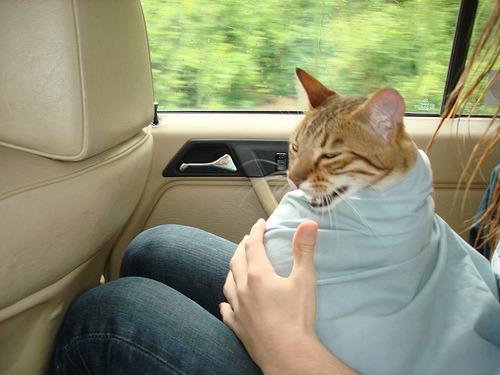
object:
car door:
[135, 2, 482, 212]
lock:
[150, 104, 162, 133]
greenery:
[139, 2, 499, 128]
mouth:
[295, 183, 349, 210]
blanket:
[245, 146, 498, 370]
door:
[104, 1, 498, 302]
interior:
[4, 1, 497, 373]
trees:
[143, 3, 497, 122]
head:
[279, 60, 427, 224]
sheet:
[238, 146, 498, 373]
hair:
[410, 4, 498, 262]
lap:
[60, 268, 238, 374]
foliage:
[142, 4, 498, 113]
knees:
[90, 216, 189, 311]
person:
[45, 100, 492, 375]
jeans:
[43, 216, 230, 375]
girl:
[42, 96, 498, 373]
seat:
[2, 0, 158, 371]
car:
[0, 2, 500, 371]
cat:
[264, 62, 459, 281]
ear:
[363, 85, 404, 145]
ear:
[292, 65, 338, 108]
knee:
[48, 273, 169, 371]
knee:
[118, 223, 220, 299]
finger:
[243, 216, 275, 278]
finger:
[219, 265, 246, 313]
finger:
[215, 298, 236, 329]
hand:
[216, 212, 318, 372]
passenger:
[45, 0, 498, 375]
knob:
[149, 96, 162, 126]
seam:
[50, 322, 190, 372]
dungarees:
[42, 223, 262, 370]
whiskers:
[237, 153, 367, 248]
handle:
[178, 150, 239, 170]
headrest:
[1, 0, 157, 161]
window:
[137, 0, 498, 115]